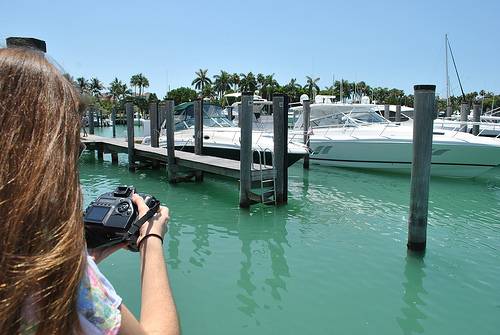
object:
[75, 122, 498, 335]
water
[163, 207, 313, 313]
ripples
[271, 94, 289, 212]
posts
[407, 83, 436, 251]
post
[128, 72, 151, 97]
palm trees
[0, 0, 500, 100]
sky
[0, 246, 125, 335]
shirt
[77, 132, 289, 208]
dock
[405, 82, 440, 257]
pillars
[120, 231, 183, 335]
arm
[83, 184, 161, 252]
camera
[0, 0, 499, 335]
photo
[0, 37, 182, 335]
girl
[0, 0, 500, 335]
harbor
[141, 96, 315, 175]
boat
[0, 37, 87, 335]
hair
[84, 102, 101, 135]
pier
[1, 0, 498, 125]
distance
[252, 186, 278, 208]
stairs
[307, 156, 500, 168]
stripe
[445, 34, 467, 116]
mast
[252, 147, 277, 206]
ladder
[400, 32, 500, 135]
sailboat